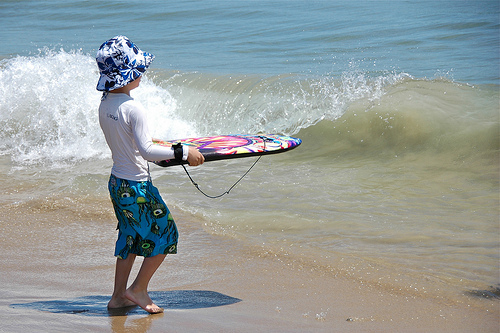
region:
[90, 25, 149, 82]
a blue and white hat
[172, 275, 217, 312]
the shadow on the sand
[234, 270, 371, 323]
the sand is brown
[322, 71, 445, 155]
a small wave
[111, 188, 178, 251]
person is wearing shorts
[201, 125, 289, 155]
a boogie board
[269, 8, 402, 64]
the water is blue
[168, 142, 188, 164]
a strap on the boogie board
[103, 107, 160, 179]
a long sleeve white shirt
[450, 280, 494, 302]
a shadow in the water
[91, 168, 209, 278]
the short is blue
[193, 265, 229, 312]
the sand is wet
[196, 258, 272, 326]
the sand is wet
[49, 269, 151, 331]
the sand is wet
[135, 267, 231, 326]
the sand is wet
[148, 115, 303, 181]
child holding a surfboard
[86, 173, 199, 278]
boy wearing blue shorts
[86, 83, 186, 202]
boy wearing a white shirt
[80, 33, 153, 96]
boy wearing a blue and white hat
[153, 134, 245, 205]
surfboard attached to boys arm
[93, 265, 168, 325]
boy standing barefoot in sand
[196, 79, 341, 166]
waves crashing on beach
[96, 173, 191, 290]
boy wearing yellow and blue shorts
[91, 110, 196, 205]
boy wearing long sleeve shirt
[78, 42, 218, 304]
boy heading towards water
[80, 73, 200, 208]
the shirt is white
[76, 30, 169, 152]
boy wearing a hat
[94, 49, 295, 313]
person standing on the beach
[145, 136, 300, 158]
board in person's hand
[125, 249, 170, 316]
leg of person on beach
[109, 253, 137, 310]
leg of person on beach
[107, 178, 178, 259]
blue shorts of person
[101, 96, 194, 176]
white shirt of person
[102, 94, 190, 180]
white shirt with long sleeves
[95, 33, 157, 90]
hat of person at beach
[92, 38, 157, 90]
hat is white and blue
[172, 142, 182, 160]
writs band attached to board